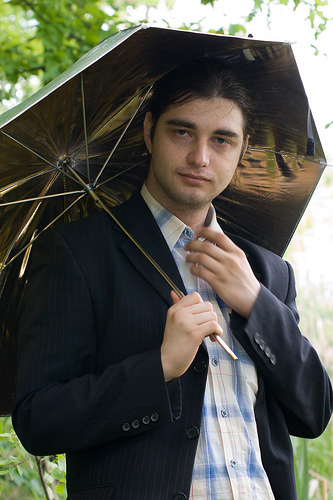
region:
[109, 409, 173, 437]
Buttons on the jacket.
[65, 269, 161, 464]
The jacket has pin stripes.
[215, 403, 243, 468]
Buttons on the shirt.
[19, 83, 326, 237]
The man is under an umbrella.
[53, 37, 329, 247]
Man is holding an umbrella.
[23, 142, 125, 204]
Rods on the umbrella.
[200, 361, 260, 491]
The shirt is blue and white.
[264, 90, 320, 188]
Reflection in the umbrella.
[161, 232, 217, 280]
The man hand is touching his neck.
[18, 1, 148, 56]
A green tree behind the man.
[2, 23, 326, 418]
a black shiny umbrella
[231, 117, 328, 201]
a shadow casting off umbrella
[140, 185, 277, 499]
a checkered shirt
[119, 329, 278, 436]
the four buttons on each sleeve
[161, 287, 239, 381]
the right hand on handle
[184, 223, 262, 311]
the left hand up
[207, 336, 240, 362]
the pointy handle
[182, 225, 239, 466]
the buttons on shirt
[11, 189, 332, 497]
the striped blue blazer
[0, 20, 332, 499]
a man standing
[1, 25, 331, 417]
silver and black umbrella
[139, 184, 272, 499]
a blue plaid shirt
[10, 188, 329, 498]
a pinstriped jacket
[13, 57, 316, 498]
a dark haired man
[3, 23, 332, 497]
a dark haired man hold an umbrella over his head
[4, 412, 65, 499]
green vegetation behind the man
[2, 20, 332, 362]
umbrella with a metal handle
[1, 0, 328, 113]
a tree is in the background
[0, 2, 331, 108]
the tree has green leaves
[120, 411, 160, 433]
four dark buttons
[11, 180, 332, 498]
person is wearing pinstripe blazer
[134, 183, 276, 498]
person has on blue plaid shirt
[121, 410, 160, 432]
four black buttons on bottom arm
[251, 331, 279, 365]
four black buttons on higher arm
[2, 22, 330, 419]
umbrella has mylar top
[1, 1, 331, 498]
green leaves behind person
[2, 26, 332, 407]
umbrella poles are metal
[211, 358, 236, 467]
shirt has buttons in row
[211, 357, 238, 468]
three buttons on shirt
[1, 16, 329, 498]
A man holding an umbrella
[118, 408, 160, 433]
Four buttons in a row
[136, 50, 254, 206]
Man has brown hair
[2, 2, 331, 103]
Green leaves on a tree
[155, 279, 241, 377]
Umbrella handle in a hand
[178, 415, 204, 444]
A black button on a jacket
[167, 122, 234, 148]
A pair of two eyes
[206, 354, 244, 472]
Three buttons on a shirt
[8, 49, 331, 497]
The man is wearing a suit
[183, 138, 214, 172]
Nose on man's face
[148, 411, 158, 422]
black button on jacket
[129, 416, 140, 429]
black button on jacket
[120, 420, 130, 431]
black button on jacket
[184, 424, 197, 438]
black button on jacket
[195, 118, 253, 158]
eye of the man